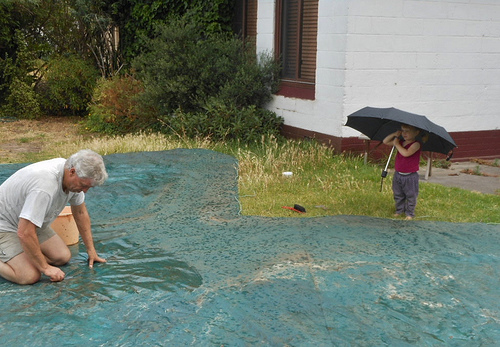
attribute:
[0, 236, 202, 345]
surface — wet, greenish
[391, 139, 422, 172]
shirt — pink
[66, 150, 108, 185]
hair — white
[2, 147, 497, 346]
plastic — green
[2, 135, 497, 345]
tarp — large, green